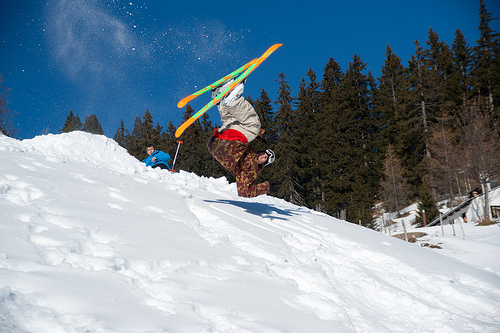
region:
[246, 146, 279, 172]
the head of a man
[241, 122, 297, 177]
the head of a man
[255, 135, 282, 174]
the head of a man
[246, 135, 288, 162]
the head of a man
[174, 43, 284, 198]
Skier performing trick on the snow.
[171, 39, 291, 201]
skier jumping upside down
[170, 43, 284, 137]
green and orange skis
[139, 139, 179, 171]
man in blue jacket lying in snow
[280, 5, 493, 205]
tall green pine trees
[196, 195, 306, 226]
shadow of skier on snow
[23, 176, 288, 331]
white snow with footprints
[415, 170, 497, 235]
small white house near trees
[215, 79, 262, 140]
white snow pants on skier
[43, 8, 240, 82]
snow flying through air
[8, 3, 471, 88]
dark blue sky above tree tops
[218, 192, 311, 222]
a shadow on the snow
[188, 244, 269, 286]
the snow is white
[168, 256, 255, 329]
the snow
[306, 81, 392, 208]
the tree is tall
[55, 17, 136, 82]
snow in the air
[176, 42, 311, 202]
the man is upside down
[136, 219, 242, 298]
the white snow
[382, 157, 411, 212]
a small tree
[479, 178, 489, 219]
a tree trunk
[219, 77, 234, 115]
boy has white shoes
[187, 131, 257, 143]
boy has red shirt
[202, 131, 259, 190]
boy has brown coat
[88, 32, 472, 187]
green trees behind boys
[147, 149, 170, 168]
boy has blue coat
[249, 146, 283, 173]
boy is wearing goggles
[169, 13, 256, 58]
blue and clear sky